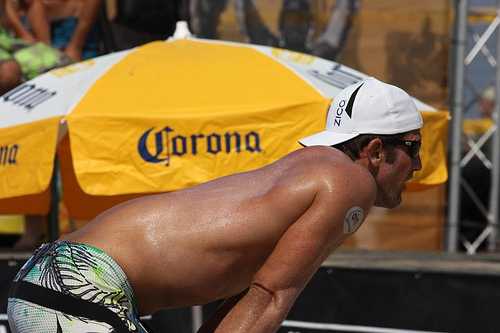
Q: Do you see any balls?
A: No, there are no balls.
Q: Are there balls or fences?
A: No, there are no balls or fences.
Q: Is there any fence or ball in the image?
A: No, there are no balls or fences.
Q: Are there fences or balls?
A: No, there are no balls or fences.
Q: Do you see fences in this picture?
A: No, there are no fences.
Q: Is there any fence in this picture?
A: No, there are no fences.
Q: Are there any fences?
A: No, there are no fences.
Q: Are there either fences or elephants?
A: No, there are no fences or elephants.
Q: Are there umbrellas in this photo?
A: Yes, there is an umbrella.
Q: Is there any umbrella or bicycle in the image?
A: Yes, there is an umbrella.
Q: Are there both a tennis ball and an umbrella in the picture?
A: No, there is an umbrella but no tennis balls.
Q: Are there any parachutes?
A: No, there are no parachutes.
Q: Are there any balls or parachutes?
A: No, there are no parachutes or balls.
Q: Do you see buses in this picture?
A: No, there are no buses.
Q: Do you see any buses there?
A: No, there are no buses.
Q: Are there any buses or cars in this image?
A: No, there are no buses or cars.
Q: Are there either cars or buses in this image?
A: No, there are no buses or cars.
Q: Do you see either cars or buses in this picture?
A: No, there are no buses or cars.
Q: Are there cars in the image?
A: No, there are no cars.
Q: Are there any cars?
A: No, there are no cars.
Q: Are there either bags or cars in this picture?
A: No, there are no cars or bags.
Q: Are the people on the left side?
A: Yes, the people are on the left of the image.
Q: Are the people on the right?
A: No, the people are on the left of the image.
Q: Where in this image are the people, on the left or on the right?
A: The people are on the left of the image.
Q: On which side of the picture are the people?
A: The people are on the left of the image.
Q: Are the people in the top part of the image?
A: Yes, the people are in the top of the image.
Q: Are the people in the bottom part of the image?
A: No, the people are in the top of the image.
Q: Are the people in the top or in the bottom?
A: The people are in the top of the image.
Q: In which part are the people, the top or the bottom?
A: The people are in the top of the image.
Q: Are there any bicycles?
A: No, there are no bicycles.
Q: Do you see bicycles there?
A: No, there are no bicycles.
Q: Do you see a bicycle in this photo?
A: No, there are no bicycles.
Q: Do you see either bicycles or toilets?
A: No, there are no bicycles or toilets.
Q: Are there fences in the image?
A: No, there are no fences.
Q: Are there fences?
A: No, there are no fences.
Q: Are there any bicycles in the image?
A: No, there are no bicycles.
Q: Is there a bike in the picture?
A: No, there are no bikes.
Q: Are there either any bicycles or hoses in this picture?
A: No, there are no bicycles or hoses.